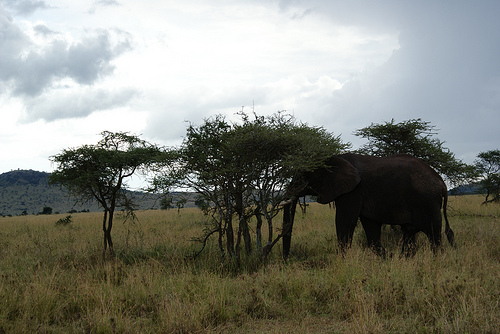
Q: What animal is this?
A: Elephant.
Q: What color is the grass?
A: Green.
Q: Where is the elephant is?
A: Outside in field.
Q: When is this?
A: During the day time.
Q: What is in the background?
A: Hills.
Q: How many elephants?
A: One.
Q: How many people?
A: None.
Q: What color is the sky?
A: White.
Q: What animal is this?
A: Elephant.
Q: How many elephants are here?
A: 1.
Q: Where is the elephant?
A: Standing by the trees.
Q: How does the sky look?
A: Gray and cloudy.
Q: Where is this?
A: Savannah.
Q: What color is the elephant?
A: Gray.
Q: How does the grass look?
A: Dry and overgrown.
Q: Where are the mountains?
A: In the distance.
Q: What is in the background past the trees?
A: Hills.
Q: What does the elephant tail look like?
A: Long with a hairy end.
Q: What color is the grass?
A: Yellow.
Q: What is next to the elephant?
A: Trees.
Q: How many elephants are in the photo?
A: One.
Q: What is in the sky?
A: Clouds.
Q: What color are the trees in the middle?
A: Green.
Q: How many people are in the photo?
A: None.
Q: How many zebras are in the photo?
A: None.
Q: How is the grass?
A: Dry looking.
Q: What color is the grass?
A: Green and brown.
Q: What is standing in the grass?
A: An elephant.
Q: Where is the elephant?
A: In a field.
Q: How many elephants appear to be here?
A: One.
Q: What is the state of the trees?
A: They are leafy, but appear spindly, as if young, or stunted.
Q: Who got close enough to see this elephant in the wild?
A: The photographer.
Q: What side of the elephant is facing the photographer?
A: The left side.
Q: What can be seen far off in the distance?
A: Hills.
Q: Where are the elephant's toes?
A: Covered by grass.